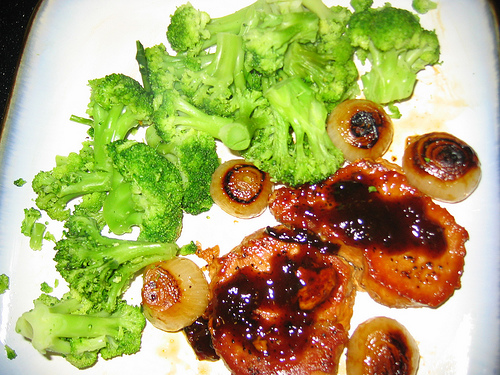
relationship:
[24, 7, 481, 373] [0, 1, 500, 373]
food on plate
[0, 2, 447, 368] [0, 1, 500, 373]
broccoli on plate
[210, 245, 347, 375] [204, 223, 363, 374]
sauce on fillets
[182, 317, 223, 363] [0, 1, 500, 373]
sauce on plate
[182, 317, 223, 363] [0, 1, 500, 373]
sauce in plate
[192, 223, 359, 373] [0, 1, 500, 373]
fillets are in plate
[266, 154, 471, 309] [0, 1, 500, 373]
fillets are in plate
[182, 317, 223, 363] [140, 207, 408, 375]
sauce seafood cooked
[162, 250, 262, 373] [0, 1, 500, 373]
sauce on plate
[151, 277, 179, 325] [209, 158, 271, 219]
ring on food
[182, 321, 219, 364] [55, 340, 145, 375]
sauce on plate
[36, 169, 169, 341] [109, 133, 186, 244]
top of broccoli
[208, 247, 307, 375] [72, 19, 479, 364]
black circle around piece of food